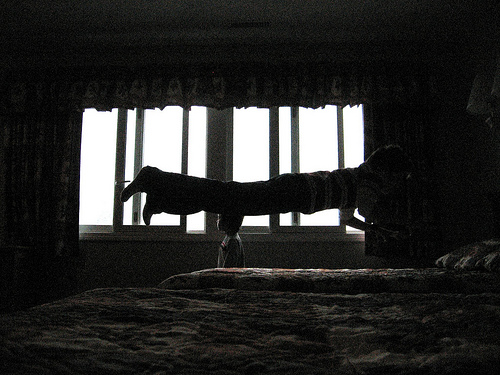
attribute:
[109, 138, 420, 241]
man — levitating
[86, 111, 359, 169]
window — larg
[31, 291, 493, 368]
bed — made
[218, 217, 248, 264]
boy — standing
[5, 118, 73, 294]
curtain — open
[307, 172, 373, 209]
shirt — striped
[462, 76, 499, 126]
lamp — mounted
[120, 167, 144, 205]
foot — shoeless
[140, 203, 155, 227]
foot — shoeless